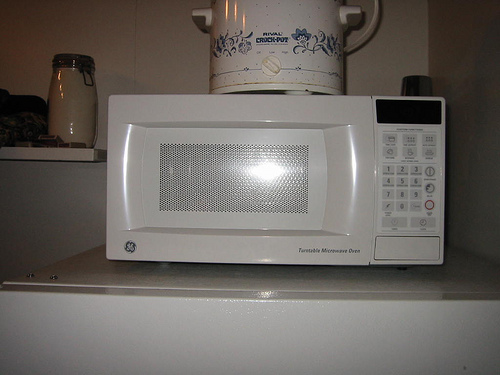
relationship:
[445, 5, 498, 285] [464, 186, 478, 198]
wall seen part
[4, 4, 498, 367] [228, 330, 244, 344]
kitchen seen part